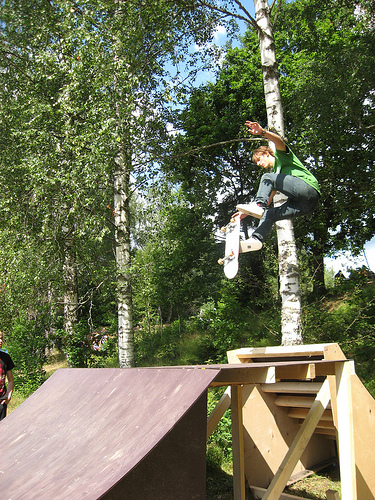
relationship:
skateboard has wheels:
[224, 213, 241, 278] [216, 250, 235, 267]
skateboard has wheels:
[224, 213, 241, 278] [217, 215, 238, 234]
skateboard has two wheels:
[222, 213, 242, 277] [220, 215, 235, 235]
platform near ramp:
[149, 362, 341, 394] [6, 362, 220, 497]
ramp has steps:
[226, 342, 373, 498] [262, 380, 337, 441]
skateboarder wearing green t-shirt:
[237, 121, 322, 252] [268, 148, 324, 197]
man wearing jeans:
[216, 121, 321, 261] [252, 174, 310, 237]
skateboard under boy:
[224, 213, 241, 278] [232, 116, 325, 254]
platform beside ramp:
[149, 362, 341, 394] [6, 362, 220, 497]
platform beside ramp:
[149, 362, 341, 394] [226, 342, 373, 498]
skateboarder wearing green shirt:
[237, 121, 322, 252] [267, 143, 323, 198]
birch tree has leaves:
[41, 16, 92, 354] [95, 60, 115, 85]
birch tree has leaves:
[41, 16, 92, 354] [91, 131, 110, 157]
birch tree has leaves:
[41, 16, 92, 354] [49, 103, 73, 135]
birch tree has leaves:
[41, 16, 92, 354] [50, 149, 68, 178]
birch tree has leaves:
[41, 16, 92, 354] [62, 202, 94, 223]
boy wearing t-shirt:
[1, 330, 23, 422] [1, 341, 18, 399]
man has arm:
[217, 121, 311, 276] [243, 119, 285, 151]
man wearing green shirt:
[216, 121, 321, 261] [267, 143, 323, 198]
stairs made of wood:
[222, 343, 363, 366] [222, 332, 373, 461]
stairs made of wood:
[251, 380, 365, 402] [222, 332, 373, 461]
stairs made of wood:
[271, 400, 367, 422] [222, 332, 373, 461]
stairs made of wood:
[294, 414, 367, 456] [222, 332, 373, 461]